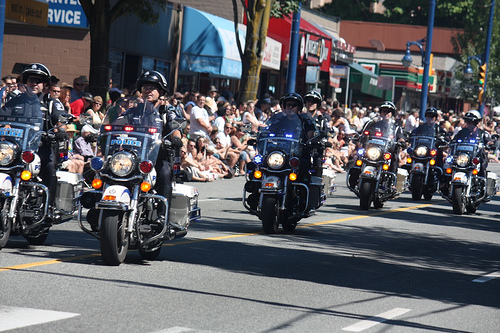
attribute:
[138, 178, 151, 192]
light — orange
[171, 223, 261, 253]
line — yellow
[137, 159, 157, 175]
light — red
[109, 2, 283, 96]
building — row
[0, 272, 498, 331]
street — smooth, paved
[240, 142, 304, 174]
light — white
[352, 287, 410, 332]
lines — white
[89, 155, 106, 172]
light — blue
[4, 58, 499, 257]
group — large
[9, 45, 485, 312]
public event — big